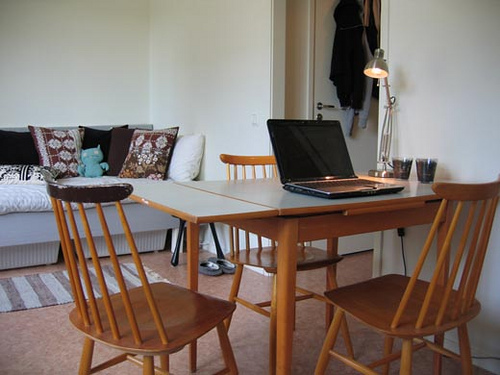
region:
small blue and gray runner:
[13, 265, 66, 321]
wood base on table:
[254, 218, 332, 247]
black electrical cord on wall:
[391, 225, 418, 267]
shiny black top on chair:
[36, 169, 149, 215]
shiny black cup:
[407, 145, 452, 182]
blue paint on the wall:
[423, 100, 495, 150]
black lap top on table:
[250, 105, 401, 205]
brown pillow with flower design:
[110, 118, 194, 175]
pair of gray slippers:
[196, 253, 244, 283]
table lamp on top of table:
[333, 39, 411, 159]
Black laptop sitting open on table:
[268, 114, 407, 197]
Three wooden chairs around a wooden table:
[40, 150, 499, 372]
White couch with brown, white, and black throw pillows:
[0, 126, 204, 265]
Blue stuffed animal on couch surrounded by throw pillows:
[77, 146, 112, 180]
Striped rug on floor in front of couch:
[0, 259, 170, 311]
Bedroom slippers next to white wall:
[196, 253, 238, 279]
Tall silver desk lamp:
[362, 45, 403, 180]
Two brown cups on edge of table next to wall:
[393, 152, 439, 186]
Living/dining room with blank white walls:
[4, 4, 499, 369]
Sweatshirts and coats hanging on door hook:
[332, 3, 391, 137]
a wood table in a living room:
[113, 178, 460, 374]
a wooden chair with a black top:
[43, 173, 241, 373]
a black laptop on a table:
[267, 121, 403, 193]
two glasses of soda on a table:
[395, 156, 437, 185]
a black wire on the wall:
[396, 229, 409, 274]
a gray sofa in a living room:
[0, 125, 200, 269]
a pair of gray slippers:
[199, 256, 234, 278]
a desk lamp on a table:
[363, 43, 395, 177]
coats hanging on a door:
[328, 0, 383, 137]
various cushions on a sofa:
[3, 127, 180, 177]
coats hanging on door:
[330, 4, 372, 115]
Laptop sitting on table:
[262, 115, 402, 197]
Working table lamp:
[363, 45, 392, 180]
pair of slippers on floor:
[203, 251, 235, 278]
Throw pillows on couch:
[10, 125, 180, 179]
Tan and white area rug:
[3, 272, 63, 309]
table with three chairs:
[48, 153, 499, 370]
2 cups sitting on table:
[394, 151, 441, 186]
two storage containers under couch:
[6, 235, 169, 272]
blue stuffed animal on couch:
[78, 142, 115, 180]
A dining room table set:
[45, 154, 498, 374]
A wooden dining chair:
[46, 181, 236, 374]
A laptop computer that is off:
[265, 117, 405, 201]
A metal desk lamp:
[362, 48, 397, 178]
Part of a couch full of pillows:
[1, 120, 203, 266]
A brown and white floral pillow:
[117, 126, 178, 178]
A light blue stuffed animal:
[76, 146, 110, 176]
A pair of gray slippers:
[196, 257, 238, 277]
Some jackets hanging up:
[328, 1, 380, 137]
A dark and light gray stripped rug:
[0, 261, 172, 312]